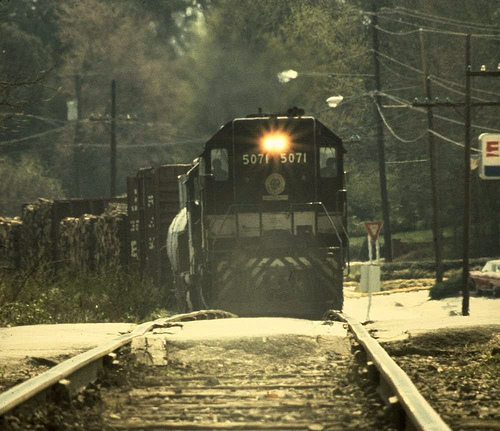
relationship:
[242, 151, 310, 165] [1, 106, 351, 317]
numbers are on front of train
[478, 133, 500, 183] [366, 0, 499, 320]
sign by telephone wires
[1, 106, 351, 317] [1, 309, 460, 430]
train on tracks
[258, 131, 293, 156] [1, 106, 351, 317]
light on front of train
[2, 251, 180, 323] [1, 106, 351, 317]
grass next to train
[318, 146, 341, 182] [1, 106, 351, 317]
window on right side of train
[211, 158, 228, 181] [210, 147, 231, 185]
person in window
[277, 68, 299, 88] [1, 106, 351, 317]
street light above train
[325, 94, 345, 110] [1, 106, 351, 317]
street light above train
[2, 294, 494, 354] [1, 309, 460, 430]
road crossing tracks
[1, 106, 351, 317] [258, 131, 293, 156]
train has light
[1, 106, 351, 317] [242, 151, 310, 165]
train has numbers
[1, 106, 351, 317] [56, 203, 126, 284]
train hauling cargo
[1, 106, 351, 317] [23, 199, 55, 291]
train hauling cargo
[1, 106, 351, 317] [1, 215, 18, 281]
train hauling cargo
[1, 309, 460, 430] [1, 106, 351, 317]
tracks are for a train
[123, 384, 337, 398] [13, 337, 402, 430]
plank in gravel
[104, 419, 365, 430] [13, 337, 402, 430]
plank in gravel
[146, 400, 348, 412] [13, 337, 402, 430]
plank in gravel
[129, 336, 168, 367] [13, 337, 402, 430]
plank in gravel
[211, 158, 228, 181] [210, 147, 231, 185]
person seen in window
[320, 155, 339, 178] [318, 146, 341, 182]
person seen in window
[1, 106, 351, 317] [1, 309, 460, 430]
train coming down tracks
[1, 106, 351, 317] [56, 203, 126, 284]
train pulling cargo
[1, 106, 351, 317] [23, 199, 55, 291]
train pulling cargo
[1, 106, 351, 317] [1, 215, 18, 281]
train pulling cargo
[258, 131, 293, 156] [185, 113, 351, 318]
light on locomotive engine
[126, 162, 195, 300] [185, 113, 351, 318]
box car behind locomotive engine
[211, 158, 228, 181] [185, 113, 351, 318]
person in locomotive engine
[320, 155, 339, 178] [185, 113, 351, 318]
person in locomotive engine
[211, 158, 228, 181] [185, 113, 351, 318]
person sitting in locomotive engine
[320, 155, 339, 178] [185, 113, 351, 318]
person sitting in locomotive engine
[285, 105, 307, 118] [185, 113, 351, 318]
horn on top of locomotive engine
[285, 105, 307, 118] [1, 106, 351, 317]
horn part of train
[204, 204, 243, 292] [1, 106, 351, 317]
ladder for entering train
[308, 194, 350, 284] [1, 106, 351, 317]
ladder for entering train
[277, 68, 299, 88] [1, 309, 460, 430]
street light beside tracks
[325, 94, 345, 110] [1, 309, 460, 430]
street light beside tracks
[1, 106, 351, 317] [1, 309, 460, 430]
train coming on tracks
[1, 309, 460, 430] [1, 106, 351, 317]
tracks have train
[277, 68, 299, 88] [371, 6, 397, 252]
street light on pole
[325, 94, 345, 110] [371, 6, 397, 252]
street light on pole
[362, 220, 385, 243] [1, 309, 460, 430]
sign next to tracks